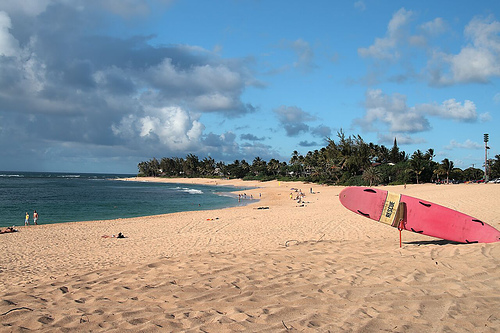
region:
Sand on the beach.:
[183, 259, 484, 330]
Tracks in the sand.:
[141, 200, 240, 252]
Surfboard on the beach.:
[333, 172, 498, 249]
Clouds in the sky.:
[14, 22, 199, 194]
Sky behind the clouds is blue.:
[171, 7, 376, 67]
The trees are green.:
[201, 144, 450, 189]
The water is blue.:
[22, 171, 162, 203]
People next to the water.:
[13, 193, 50, 242]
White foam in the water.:
[161, 173, 220, 207]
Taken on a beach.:
[1, 10, 491, 331]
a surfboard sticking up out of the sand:
[337, 174, 499, 261]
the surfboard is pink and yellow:
[340, 174, 499, 253]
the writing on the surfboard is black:
[385, 186, 397, 223]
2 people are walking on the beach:
[17, 204, 44, 231]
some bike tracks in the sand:
[179, 215, 204, 245]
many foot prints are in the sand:
[4, 262, 498, 326]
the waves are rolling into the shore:
[173, 184, 206, 199]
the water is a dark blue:
[1, 171, 235, 210]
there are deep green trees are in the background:
[133, 135, 489, 183]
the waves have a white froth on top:
[176, 184, 206, 198]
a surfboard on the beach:
[304, 146, 495, 293]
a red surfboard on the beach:
[248, 137, 493, 311]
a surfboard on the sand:
[314, 147, 498, 293]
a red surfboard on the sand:
[307, 134, 497, 276]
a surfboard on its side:
[311, 147, 496, 296]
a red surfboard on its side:
[342, 93, 497, 314]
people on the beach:
[215, 143, 346, 282]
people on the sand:
[186, 126, 401, 329]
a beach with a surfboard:
[244, 171, 499, 308]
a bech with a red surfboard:
[224, 131, 495, 308]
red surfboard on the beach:
[339, 183, 499, 243]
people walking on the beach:
[23, 209, 37, 225]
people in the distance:
[287, 184, 317, 209]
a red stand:
[395, 223, 404, 246]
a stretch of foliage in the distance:
[137, 130, 485, 184]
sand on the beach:
[3, 248, 483, 332]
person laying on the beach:
[0, 223, 17, 234]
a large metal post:
[482, 133, 490, 175]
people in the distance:
[231, 189, 264, 206]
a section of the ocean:
[0, 169, 257, 227]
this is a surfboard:
[341, 183, 482, 232]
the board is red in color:
[429, 212, 483, 234]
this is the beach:
[254, 240, 314, 307]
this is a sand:
[228, 255, 350, 322]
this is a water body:
[65, 161, 118, 196]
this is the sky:
[240, 1, 356, 75]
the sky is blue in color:
[190, 10, 249, 32]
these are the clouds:
[357, 40, 400, 60]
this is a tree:
[331, 152, 342, 178]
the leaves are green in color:
[408, 157, 423, 164]